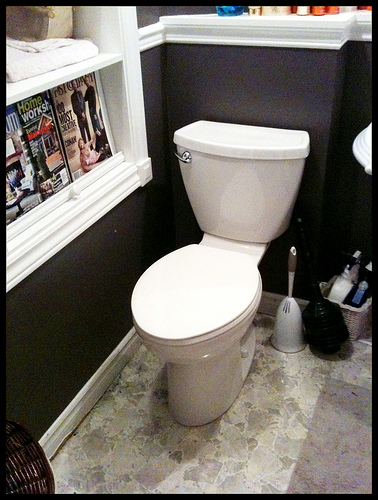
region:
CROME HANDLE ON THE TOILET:
[175, 151, 191, 165]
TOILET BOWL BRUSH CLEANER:
[276, 246, 301, 350]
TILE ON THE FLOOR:
[241, 434, 302, 465]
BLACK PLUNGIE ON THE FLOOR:
[322, 308, 331, 331]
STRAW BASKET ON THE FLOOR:
[350, 312, 358, 323]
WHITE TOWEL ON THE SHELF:
[31, 54, 53, 66]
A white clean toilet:
[129, 251, 257, 426]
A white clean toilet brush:
[280, 265, 304, 355]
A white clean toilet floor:
[172, 444, 332, 491]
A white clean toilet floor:
[128, 357, 163, 428]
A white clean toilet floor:
[316, 372, 367, 487]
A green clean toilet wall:
[186, 41, 310, 123]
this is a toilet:
[125, 111, 311, 422]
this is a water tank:
[169, 114, 310, 242]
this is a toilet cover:
[132, 240, 257, 341]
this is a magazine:
[52, 70, 116, 175]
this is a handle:
[173, 148, 192, 165]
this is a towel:
[4, 25, 105, 79]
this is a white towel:
[6, 28, 94, 71]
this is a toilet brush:
[270, 244, 306, 358]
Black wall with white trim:
[270, 20, 339, 65]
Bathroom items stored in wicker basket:
[335, 268, 369, 323]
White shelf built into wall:
[8, 11, 135, 277]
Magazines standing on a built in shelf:
[18, 89, 109, 214]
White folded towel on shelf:
[14, 37, 91, 93]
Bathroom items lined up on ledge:
[217, 6, 343, 22]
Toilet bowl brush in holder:
[273, 246, 301, 351]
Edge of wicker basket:
[7, 424, 43, 492]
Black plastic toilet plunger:
[305, 300, 341, 345]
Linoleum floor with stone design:
[70, 434, 287, 490]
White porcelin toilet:
[127, 116, 312, 429]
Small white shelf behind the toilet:
[153, 7, 373, 52]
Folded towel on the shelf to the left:
[5, 31, 102, 85]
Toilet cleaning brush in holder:
[264, 244, 307, 355]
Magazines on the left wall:
[4, 65, 123, 228]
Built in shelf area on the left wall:
[6, 4, 158, 293]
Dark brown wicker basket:
[1, 407, 60, 498]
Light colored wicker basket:
[314, 271, 375, 345]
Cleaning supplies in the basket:
[324, 252, 376, 310]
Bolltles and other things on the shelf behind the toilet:
[212, 1, 377, 23]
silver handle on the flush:
[173, 144, 191, 168]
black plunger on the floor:
[304, 252, 346, 367]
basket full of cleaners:
[324, 248, 376, 314]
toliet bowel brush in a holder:
[277, 245, 303, 358]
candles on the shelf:
[208, 4, 372, 20]